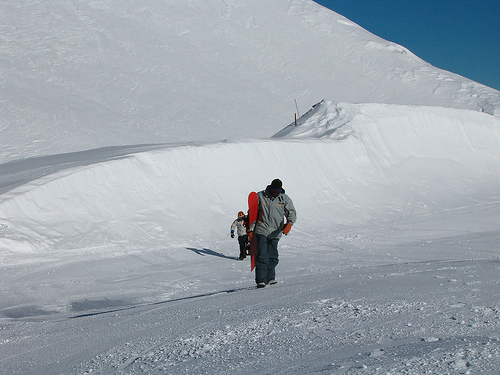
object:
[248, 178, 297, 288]
man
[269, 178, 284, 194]
cap on his head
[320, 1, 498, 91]
blues sky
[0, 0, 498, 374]
snow day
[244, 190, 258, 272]
red snowboard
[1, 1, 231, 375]
white snow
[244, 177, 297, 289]
snowboarder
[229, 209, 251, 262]
man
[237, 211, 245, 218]
yellow helmet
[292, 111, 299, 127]
pole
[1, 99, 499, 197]
ridge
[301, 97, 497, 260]
snow build up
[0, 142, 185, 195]
shadows in the snow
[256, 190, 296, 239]
silver ski jacket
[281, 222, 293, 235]
red ski gloves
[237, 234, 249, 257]
black ski pants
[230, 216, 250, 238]
white ski jacket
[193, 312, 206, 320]
small snow balls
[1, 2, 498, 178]
snow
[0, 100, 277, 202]
slope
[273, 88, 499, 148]
snow ridges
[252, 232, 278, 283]
grey ski pants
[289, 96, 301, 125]
markers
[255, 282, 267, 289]
with shoes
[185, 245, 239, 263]
shadow